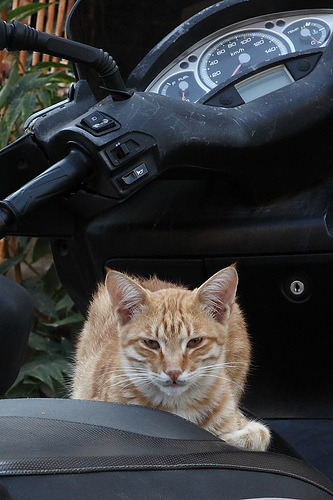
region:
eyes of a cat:
[134, 335, 205, 353]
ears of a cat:
[101, 263, 238, 320]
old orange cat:
[68, 269, 283, 460]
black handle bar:
[0, 140, 95, 215]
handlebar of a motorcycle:
[12, 136, 92, 230]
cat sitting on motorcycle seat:
[63, 258, 321, 483]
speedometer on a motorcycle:
[201, 23, 289, 98]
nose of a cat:
[161, 361, 188, 394]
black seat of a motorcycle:
[0, 393, 257, 498]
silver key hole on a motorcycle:
[287, 277, 307, 301]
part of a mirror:
[236, 26, 273, 80]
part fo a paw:
[235, 410, 267, 447]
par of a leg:
[205, 394, 229, 448]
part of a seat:
[98, 417, 136, 461]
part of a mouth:
[173, 373, 208, 414]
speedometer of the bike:
[206, 35, 288, 83]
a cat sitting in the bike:
[79, 264, 271, 457]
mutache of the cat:
[190, 365, 247, 385]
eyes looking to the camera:
[133, 323, 214, 358]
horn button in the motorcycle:
[118, 163, 147, 181]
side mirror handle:
[0, 14, 124, 81]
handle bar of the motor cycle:
[21, 13, 332, 244]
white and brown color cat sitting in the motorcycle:
[83, 274, 233, 447]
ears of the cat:
[97, 266, 251, 314]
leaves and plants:
[6, 62, 52, 102]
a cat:
[89, 276, 257, 412]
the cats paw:
[232, 418, 275, 453]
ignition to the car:
[283, 273, 308, 300]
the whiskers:
[199, 364, 238, 382]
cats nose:
[164, 366, 182, 378]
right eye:
[138, 333, 160, 352]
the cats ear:
[97, 270, 145, 303]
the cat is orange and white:
[70, 277, 276, 422]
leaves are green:
[27, 348, 61, 387]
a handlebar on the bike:
[17, 188, 58, 198]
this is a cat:
[66, 266, 258, 400]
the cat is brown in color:
[64, 270, 246, 409]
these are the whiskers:
[210, 354, 248, 383]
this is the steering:
[1, 107, 173, 228]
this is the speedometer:
[229, 21, 302, 51]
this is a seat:
[41, 416, 179, 498]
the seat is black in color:
[0, 412, 168, 492]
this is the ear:
[196, 264, 232, 306]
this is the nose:
[168, 365, 180, 375]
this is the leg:
[222, 411, 273, 449]